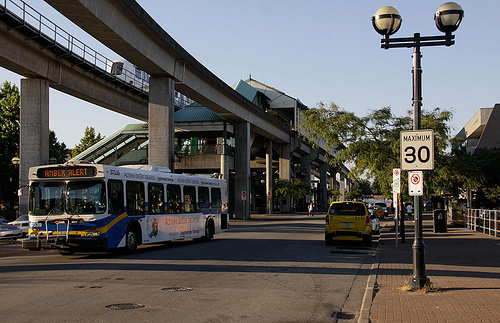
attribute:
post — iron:
[407, 28, 432, 293]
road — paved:
[1, 210, 372, 322]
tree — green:
[302, 100, 500, 242]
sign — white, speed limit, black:
[399, 132, 435, 170]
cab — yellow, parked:
[325, 202, 373, 248]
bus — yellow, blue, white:
[30, 161, 231, 243]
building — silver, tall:
[66, 79, 307, 214]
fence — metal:
[3, 2, 161, 101]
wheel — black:
[129, 227, 141, 252]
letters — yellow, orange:
[39, 165, 89, 176]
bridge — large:
[1, 4, 160, 207]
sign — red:
[266, 189, 273, 201]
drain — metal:
[334, 306, 356, 322]